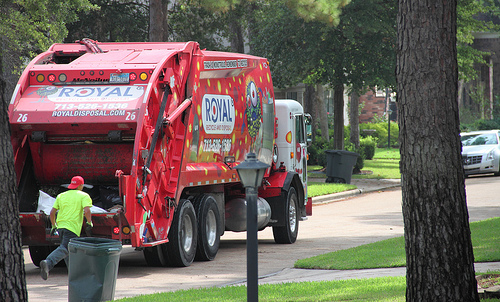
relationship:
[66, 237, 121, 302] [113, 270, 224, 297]
can on sidewalk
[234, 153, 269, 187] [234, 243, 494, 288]
lamp on sidewalk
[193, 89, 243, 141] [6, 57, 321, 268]
sign on truck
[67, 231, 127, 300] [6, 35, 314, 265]
trash in truck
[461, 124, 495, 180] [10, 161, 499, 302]
parked car on road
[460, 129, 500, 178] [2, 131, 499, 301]
parked car on street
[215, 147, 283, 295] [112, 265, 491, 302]
post in yard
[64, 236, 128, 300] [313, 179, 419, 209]
can on corner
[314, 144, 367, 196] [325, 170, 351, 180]
trash can with wheels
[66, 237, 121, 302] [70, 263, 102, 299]
can with dent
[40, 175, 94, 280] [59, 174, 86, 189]
bears with hat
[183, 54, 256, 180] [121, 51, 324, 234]
dots on truck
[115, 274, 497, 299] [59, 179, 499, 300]
grass on sides of sidewalk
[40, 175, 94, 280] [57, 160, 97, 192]
bears wearing hat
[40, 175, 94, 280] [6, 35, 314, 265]
bears running behind truck